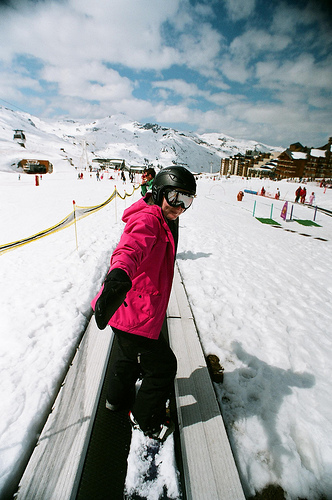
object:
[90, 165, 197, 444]
woman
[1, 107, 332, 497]
snow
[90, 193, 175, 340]
jacket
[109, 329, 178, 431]
pants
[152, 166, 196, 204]
helmet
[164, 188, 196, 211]
goggles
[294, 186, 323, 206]
people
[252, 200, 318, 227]
posts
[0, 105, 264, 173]
mountains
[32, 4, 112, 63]
clouds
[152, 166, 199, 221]
head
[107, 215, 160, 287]
arm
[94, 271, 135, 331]
hand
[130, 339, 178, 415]
leg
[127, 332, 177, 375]
thigh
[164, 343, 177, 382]
knee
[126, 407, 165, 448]
feet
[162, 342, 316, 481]
shadow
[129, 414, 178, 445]
shoe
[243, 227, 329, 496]
ground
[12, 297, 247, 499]
wood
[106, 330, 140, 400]
legs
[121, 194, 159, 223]
hood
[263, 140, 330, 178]
buildings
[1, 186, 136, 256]
yellow tape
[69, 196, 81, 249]
reflectors